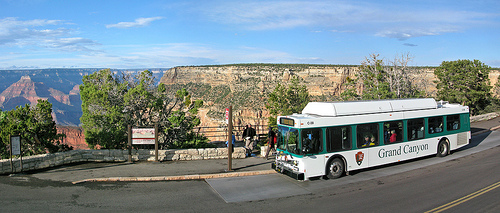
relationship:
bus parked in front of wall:
[269, 94, 474, 182] [1, 110, 484, 174]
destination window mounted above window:
[278, 116, 296, 129] [277, 126, 302, 157]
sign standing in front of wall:
[8, 132, 24, 173] [1, 110, 484, 174]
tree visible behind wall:
[79, 67, 204, 149] [1, 110, 484, 174]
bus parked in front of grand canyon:
[269, 94, 474, 182] [1, 63, 482, 146]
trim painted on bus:
[272, 110, 471, 158] [269, 94, 474, 182]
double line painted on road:
[419, 180, 485, 209] [0, 124, 483, 211]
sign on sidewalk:
[127, 121, 160, 162] [0, 152, 278, 184]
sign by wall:
[6, 130, 26, 176] [0, 145, 243, 175]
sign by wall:
[127, 121, 160, 162] [0, 146, 250, 178]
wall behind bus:
[0, 145, 243, 175] [269, 94, 474, 182]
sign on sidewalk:
[125, 119, 162, 159] [0, 155, 273, 183]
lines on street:
[442, 175, 487, 203] [404, 179, 440, 194]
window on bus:
[355, 121, 380, 145] [308, 99, 461, 169]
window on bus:
[264, 109, 302, 135] [262, 86, 457, 190]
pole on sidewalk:
[214, 105, 259, 183] [197, 154, 230, 174]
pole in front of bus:
[214, 105, 259, 183] [263, 96, 457, 184]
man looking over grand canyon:
[233, 122, 257, 173] [137, 73, 225, 171]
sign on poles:
[8, 132, 24, 173] [0, 152, 30, 189]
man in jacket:
[240, 122, 257, 157] [239, 125, 255, 144]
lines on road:
[437, 183, 479, 211] [364, 169, 438, 189]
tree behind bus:
[437, 55, 466, 105] [290, 84, 468, 192]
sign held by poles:
[130, 127, 156, 144] [126, 123, 161, 163]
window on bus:
[349, 120, 383, 147] [269, 94, 474, 182]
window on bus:
[445, 111, 465, 137] [269, 94, 474, 182]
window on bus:
[407, 120, 427, 141] [270, 91, 469, 178]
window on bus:
[384, 120, 402, 147] [269, 94, 474, 182]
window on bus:
[355, 121, 380, 145] [269, 94, 474, 182]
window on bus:
[326, 127, 354, 152] [269, 94, 474, 182]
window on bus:
[300, 128, 322, 154] [269, 94, 474, 182]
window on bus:
[277, 126, 302, 157] [269, 94, 474, 182]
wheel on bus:
[327, 159, 346, 180] [270, 91, 469, 178]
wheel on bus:
[435, 140, 449, 156] [269, 94, 474, 182]